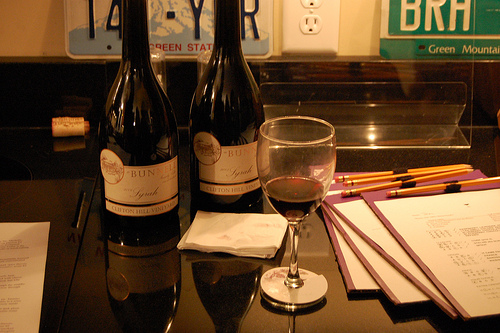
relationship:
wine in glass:
[263, 175, 328, 216] [255, 116, 337, 307]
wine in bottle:
[263, 175, 328, 216] [96, 1, 178, 224]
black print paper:
[0, 236, 29, 332] [0, 221, 52, 332]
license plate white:
[380, 2, 499, 62] [399, 1, 472, 33]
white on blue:
[61, 2, 89, 31] [65, 1, 275, 59]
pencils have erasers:
[335, 163, 498, 200] [335, 175, 357, 200]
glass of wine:
[255, 116, 337, 307] [263, 175, 328, 216]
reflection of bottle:
[99, 214, 184, 332] [96, 1, 178, 224]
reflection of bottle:
[190, 259, 263, 332] [187, 1, 264, 209]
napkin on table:
[175, 209, 289, 261] [174, 207, 287, 332]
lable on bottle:
[99, 147, 179, 218] [96, 1, 178, 224]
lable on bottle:
[192, 130, 275, 197] [187, 1, 264, 209]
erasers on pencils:
[335, 175, 357, 200] [335, 163, 498, 200]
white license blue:
[61, 2, 89, 31] [65, 1, 275, 59]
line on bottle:
[104, 191, 179, 208] [96, 1, 178, 224]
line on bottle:
[198, 175, 258, 187] [187, 1, 264, 209]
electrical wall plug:
[282, 0, 340, 58] [298, 17, 323, 37]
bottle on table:
[187, 1, 264, 209] [174, 207, 287, 332]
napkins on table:
[175, 209, 289, 261] [174, 207, 287, 332]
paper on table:
[0, 221, 52, 332] [0, 218, 130, 332]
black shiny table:
[50, 249, 332, 332] [53, 268, 257, 332]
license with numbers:
[65, 1, 275, 59] [84, 3, 123, 39]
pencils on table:
[335, 163, 498, 200] [53, 268, 257, 332]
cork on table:
[48, 114, 92, 140] [53, 268, 257, 332]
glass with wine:
[255, 116, 337, 307] [263, 175, 328, 216]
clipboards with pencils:
[328, 172, 499, 321] [335, 163, 498, 200]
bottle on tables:
[96, 1, 178, 224] [50, 249, 332, 332]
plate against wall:
[380, 2, 499, 62] [340, 2, 381, 59]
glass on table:
[255, 116, 337, 307] [53, 268, 257, 332]